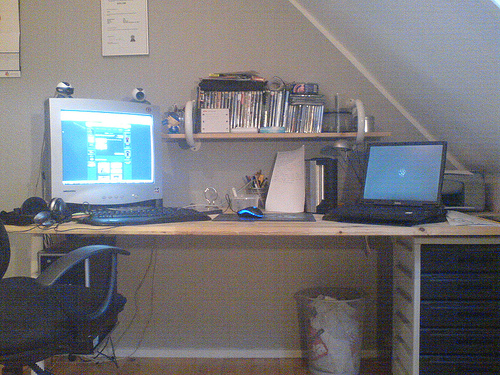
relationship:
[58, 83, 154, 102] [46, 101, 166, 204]
web cams on monitor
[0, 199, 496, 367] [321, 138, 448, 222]
desk has laptop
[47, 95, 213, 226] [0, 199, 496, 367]
pc on desk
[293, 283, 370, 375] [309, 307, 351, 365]
can for trash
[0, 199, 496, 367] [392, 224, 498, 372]
desk has drawers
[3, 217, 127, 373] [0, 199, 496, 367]
chair near desk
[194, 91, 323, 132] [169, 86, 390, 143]
games on shelf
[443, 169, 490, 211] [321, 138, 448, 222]
printer behind laptop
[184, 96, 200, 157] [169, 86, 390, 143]
bracket on shelf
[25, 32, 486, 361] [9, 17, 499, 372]
space for office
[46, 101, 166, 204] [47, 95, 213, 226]
monitor for pc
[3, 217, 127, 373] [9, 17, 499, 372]
chair for office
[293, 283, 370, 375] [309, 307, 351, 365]
can has trash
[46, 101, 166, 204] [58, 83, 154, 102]
monitor has web cams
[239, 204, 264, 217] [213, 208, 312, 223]
mouse on pad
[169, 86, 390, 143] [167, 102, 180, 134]
shelf has figurine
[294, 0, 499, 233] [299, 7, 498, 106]
roof slopes down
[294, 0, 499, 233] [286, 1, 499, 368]
roof on right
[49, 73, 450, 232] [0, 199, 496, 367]
pc on desk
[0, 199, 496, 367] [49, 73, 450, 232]
desk has pc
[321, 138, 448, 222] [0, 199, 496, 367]
laptop on desk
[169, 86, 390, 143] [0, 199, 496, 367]
shelf above desk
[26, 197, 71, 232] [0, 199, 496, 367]
headphones on desk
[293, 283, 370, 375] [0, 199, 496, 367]
can under desk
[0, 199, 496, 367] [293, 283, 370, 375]
desk over can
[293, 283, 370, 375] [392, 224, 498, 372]
can by drawers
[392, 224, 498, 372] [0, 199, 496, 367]
drawers under desk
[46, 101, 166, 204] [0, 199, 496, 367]
monitor on desk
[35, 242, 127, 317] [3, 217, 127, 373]
arm of chair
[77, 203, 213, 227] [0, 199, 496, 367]
keyboard on desk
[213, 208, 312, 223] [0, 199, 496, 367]
mouse pad on desk